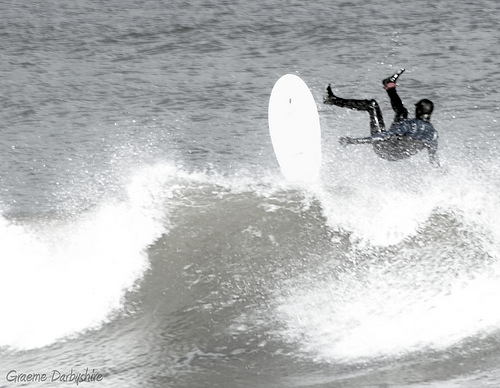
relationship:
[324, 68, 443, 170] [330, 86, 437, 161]
person wearing wet suit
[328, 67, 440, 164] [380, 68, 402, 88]
man has a foot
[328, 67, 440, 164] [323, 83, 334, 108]
man has left foot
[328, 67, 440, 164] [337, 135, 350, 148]
man has left hand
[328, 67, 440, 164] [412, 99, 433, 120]
man has head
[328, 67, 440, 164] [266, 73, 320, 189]
man falling off surfboard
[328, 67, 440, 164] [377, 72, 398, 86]
man has right foot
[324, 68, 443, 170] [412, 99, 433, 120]
person has head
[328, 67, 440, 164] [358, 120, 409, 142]
man has left arm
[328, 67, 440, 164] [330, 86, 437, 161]
man wearing a wet suit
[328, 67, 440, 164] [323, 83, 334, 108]
man has a left foot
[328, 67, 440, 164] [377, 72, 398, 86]
man has a right foot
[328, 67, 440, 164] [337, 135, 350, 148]
man has a left hand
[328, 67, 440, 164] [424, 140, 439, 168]
man has a right arm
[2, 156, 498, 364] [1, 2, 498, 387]
wave in ocean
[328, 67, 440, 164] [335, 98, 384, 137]
man has a left leg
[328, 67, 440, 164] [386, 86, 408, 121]
man has a rigth leg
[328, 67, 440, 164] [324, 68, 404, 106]
man has shoes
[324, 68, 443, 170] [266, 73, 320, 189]
surfer has a surfboard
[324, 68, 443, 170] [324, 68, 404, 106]
surfer wearing shoes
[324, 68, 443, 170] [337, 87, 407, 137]
surfer has pants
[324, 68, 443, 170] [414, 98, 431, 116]
surfer has wet hair